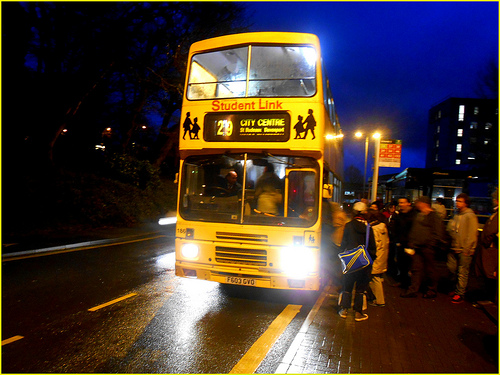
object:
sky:
[0, 2, 499, 182]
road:
[24, 241, 235, 373]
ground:
[236, 200, 288, 252]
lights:
[355, 131, 363, 139]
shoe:
[451, 294, 465, 304]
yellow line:
[226, 303, 302, 374]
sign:
[378, 143, 401, 168]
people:
[388, 198, 419, 292]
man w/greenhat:
[400, 197, 445, 299]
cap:
[353, 202, 369, 211]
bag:
[337, 245, 373, 276]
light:
[300, 47, 320, 67]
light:
[225, 71, 257, 95]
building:
[426, 97, 499, 229]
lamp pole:
[363, 137, 370, 196]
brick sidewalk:
[282, 352, 499, 375]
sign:
[203, 110, 291, 142]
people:
[446, 193, 479, 305]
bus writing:
[212, 99, 283, 111]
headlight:
[181, 243, 199, 259]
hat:
[418, 196, 430, 204]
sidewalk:
[347, 274, 494, 367]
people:
[337, 202, 378, 322]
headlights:
[278, 243, 313, 275]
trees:
[10, 5, 258, 242]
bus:
[175, 30, 344, 291]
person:
[362, 212, 391, 308]